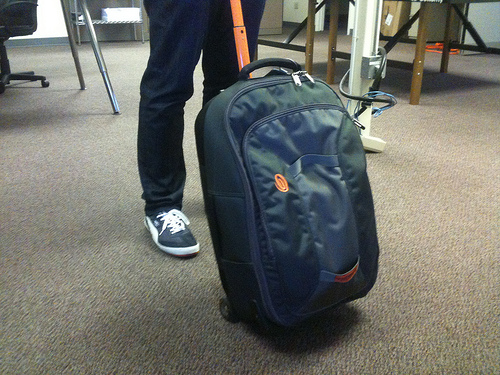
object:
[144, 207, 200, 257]
foot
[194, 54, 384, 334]
backpack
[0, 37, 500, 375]
carpet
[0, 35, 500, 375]
ground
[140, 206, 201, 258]
shoe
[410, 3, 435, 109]
legs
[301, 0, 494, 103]
table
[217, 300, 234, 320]
wheels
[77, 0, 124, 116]
legs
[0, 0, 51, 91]
chair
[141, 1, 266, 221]
pants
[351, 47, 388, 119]
wiring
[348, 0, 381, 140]
pole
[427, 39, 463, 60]
cord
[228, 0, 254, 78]
handle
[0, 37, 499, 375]
floor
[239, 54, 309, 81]
handle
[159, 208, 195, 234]
laces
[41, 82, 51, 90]
wheel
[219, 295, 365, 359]
shadow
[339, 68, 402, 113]
wires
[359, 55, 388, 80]
junction box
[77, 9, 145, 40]
shelves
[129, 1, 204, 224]
legs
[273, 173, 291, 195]
design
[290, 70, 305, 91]
zippers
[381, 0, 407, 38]
cardboard box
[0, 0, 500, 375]
background